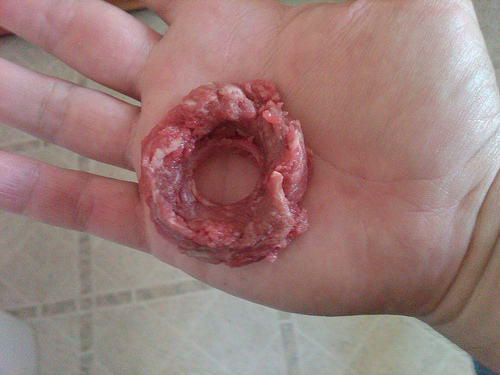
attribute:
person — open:
[6, 4, 496, 373]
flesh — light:
[342, 133, 456, 262]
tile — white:
[2, 251, 178, 367]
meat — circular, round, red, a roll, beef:
[127, 72, 323, 280]